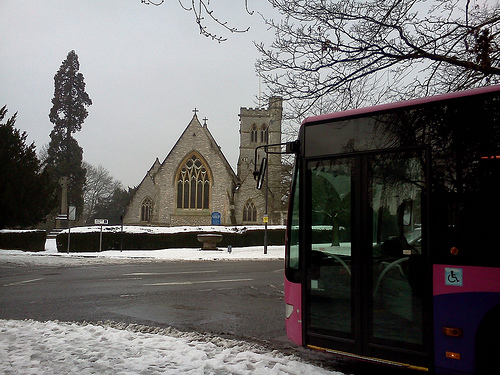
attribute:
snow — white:
[6, 227, 429, 371]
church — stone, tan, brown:
[106, 96, 298, 229]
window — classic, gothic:
[178, 152, 209, 209]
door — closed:
[304, 159, 432, 364]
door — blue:
[212, 213, 223, 226]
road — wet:
[2, 250, 494, 372]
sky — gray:
[2, 4, 492, 192]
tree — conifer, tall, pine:
[50, 48, 89, 231]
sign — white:
[94, 216, 106, 224]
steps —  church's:
[43, 213, 67, 257]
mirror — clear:
[242, 140, 287, 192]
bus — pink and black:
[250, 106, 490, 268]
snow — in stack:
[104, 342, 157, 373]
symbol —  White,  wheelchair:
[444, 266, 464, 286]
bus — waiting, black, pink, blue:
[282, 80, 497, 374]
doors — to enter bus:
[300, 150, 433, 374]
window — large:
[177, 152, 212, 209]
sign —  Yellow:
[260, 210, 277, 233]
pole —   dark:
[252, 142, 293, 287]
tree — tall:
[48, 48, 94, 218]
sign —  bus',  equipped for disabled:
[438, 268, 476, 297]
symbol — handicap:
[444, 267, 463, 285]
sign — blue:
[212, 210, 227, 226]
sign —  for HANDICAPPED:
[444, 267, 463, 286]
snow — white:
[0, 318, 325, 371]